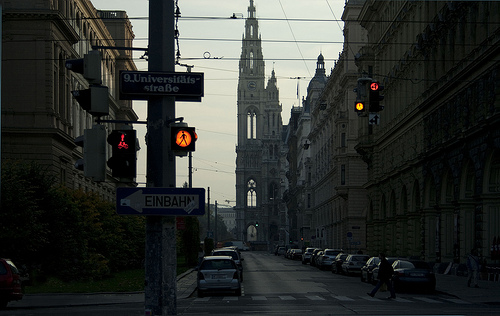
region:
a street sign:
[118, 69, 204, 100]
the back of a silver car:
[196, 256, 241, 296]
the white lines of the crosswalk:
[186, 287, 439, 302]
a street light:
[354, 76, 379, 111]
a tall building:
[235, 6, 287, 252]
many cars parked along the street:
[274, 236, 426, 292]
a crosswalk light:
[173, 128, 195, 152]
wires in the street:
[186, 8, 378, 222]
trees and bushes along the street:
[20, 185, 148, 284]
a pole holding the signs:
[145, 10, 173, 312]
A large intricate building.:
[233, 0, 284, 249]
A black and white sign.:
[116, 180, 209, 225]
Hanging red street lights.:
[353, 74, 384, 124]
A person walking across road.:
[368, 248, 400, 303]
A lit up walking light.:
[166, 122, 198, 157]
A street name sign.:
[117, 66, 204, 104]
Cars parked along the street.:
[268, 240, 440, 290]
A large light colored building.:
[0, 0, 138, 211]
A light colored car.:
[195, 255, 242, 298]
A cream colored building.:
[308, 3, 370, 253]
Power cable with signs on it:
[111, 0, 208, 312]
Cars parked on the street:
[272, 238, 456, 295]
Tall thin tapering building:
[231, 0, 287, 268]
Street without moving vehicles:
[226, 238, 498, 315]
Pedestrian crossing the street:
[168, 249, 499, 307]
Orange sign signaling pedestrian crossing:
[169, 125, 196, 152]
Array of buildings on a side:
[283, 0, 497, 298]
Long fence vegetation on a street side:
[0, 162, 230, 302]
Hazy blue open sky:
[88, 0, 358, 217]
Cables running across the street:
[1, 0, 498, 95]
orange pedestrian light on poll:
[167, 109, 204, 159]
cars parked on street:
[193, 228, 255, 299]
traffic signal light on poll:
[102, 113, 204, 310]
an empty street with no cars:
[196, 225, 431, 304]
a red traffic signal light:
[337, 33, 396, 172]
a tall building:
[222, 0, 294, 255]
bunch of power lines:
[66, 6, 484, 119]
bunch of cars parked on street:
[283, 225, 478, 297]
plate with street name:
[107, 65, 217, 107]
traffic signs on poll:
[121, 171, 215, 213]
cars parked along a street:
[202, 235, 242, 294]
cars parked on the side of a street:
[286, 233, 464, 298]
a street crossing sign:
[112, 118, 142, 160]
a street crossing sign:
[167, 113, 197, 154]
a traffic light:
[353, 73, 387, 117]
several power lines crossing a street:
[181, 9, 467, 90]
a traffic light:
[72, 43, 112, 178]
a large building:
[234, 2, 291, 251]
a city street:
[240, 234, 362, 296]